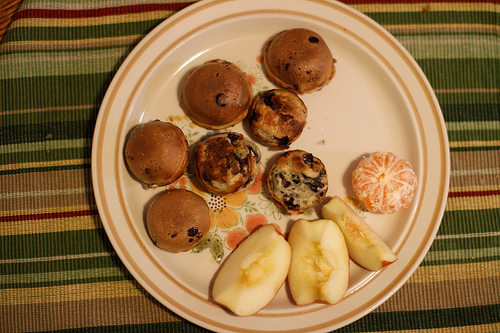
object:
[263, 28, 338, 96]
pancake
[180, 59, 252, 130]
pancake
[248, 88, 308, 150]
pancake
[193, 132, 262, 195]
pancake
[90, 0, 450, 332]
plate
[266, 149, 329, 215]
pancake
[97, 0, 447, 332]
line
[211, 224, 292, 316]
apple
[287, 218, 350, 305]
apple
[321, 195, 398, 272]
apple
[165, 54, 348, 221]
design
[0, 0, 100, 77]
table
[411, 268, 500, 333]
tablecloth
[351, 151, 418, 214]
orange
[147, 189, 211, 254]
pancake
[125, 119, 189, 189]
pancake